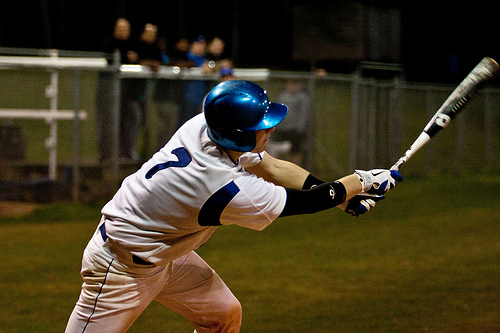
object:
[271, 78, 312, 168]
person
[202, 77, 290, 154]
blue helmet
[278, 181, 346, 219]
sleeves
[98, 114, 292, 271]
jersey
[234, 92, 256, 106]
light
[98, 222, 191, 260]
belt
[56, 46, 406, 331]
player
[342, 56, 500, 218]
baseball bat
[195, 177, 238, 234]
blue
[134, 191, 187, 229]
white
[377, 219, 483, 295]
grass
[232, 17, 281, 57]
sky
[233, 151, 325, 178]
arm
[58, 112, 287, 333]
uniform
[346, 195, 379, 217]
gloves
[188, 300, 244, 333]
stain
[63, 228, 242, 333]
man's pants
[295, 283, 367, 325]
grass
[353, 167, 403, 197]
glove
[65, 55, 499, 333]
batter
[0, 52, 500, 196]
fence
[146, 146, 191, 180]
blue seven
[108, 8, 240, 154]
fans